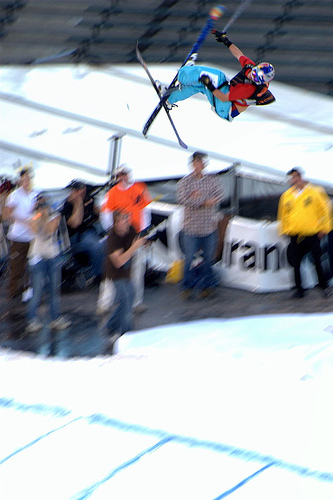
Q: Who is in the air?
A: A skier.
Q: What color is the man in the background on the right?
A: Yellow.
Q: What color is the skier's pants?
A: Blue.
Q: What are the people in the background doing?
A: Watching the skier.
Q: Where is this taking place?
A: Slopes.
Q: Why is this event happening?
A: For a skiing competition.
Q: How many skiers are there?
A: One.